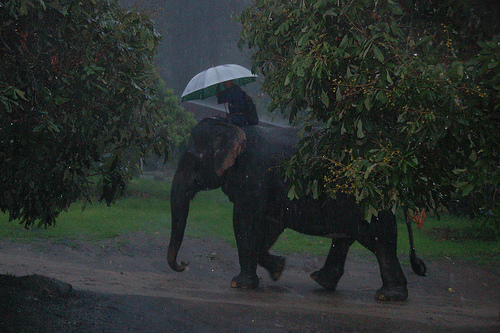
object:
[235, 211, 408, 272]
four legs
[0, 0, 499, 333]
rain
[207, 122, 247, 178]
ears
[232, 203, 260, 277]
leg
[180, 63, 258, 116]
umbrella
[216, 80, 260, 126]
driver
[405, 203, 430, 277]
tail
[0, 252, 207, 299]
puddle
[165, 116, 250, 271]
elephant's head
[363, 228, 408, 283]
leg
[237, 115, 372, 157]
back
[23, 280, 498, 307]
muddy water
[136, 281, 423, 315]
stream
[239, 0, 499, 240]
tree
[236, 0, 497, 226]
leaves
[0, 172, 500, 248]
grass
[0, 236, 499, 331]
path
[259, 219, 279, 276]
leg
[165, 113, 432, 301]
elephant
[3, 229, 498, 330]
pathway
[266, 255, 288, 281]
hoof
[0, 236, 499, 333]
ground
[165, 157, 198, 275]
trunk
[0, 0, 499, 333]
area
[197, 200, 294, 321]
walking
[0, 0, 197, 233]
trees